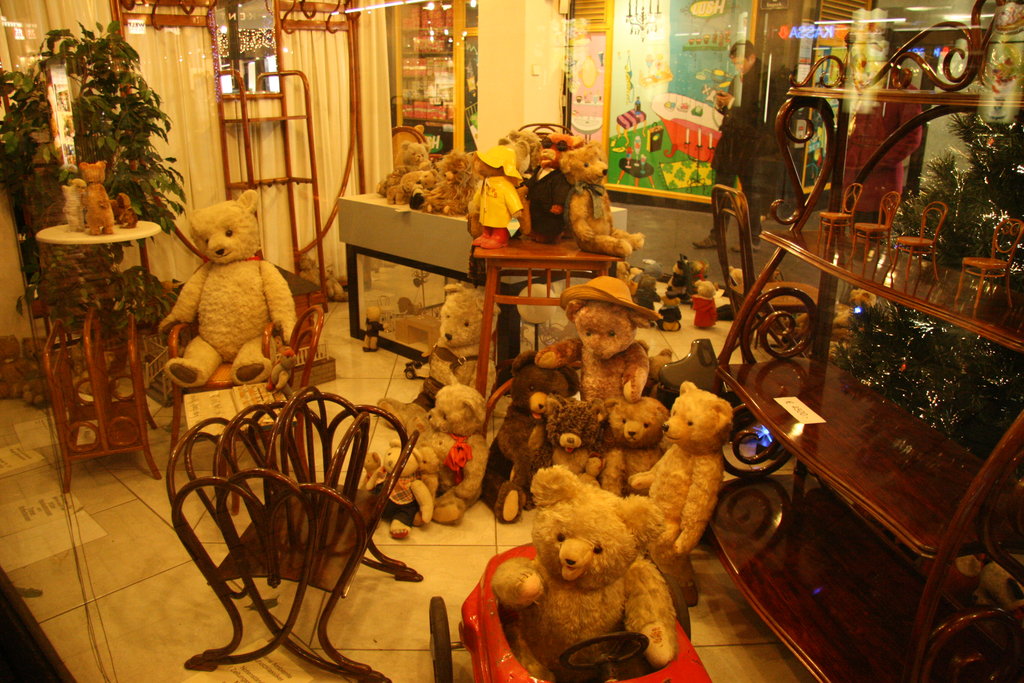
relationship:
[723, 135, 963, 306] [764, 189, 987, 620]
chairs on shelf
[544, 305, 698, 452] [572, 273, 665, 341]
teddy bear wearing hat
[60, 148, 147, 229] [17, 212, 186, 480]
statues on stand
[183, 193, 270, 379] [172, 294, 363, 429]
teddy bear in chair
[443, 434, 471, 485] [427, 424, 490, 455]
neck around neck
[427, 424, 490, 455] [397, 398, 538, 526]
neck of teddy bear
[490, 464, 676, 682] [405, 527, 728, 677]
toy in car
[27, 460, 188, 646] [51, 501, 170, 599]
floor has tile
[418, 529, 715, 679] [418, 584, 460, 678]
car has tire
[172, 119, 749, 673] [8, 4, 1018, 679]
teddy bears in store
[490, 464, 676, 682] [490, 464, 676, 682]
toy in toy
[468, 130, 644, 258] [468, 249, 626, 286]
teddy bears on table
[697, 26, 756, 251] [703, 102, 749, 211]
man dress black